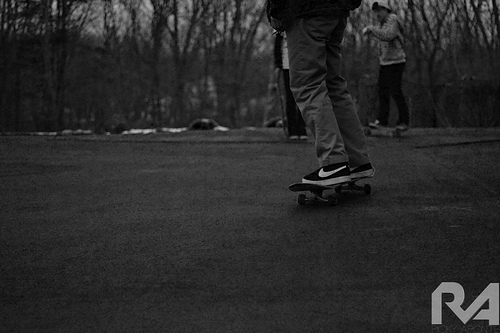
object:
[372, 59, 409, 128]
black pants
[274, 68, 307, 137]
pants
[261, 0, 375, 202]
men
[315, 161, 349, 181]
check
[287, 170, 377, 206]
skate board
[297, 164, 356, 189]
foot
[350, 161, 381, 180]
foot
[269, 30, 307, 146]
person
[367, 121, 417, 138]
skateboard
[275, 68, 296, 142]
skateboard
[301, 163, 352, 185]
shoes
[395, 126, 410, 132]
shoes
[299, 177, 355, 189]
bottom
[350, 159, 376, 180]
shoes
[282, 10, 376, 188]
pants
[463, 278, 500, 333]
letter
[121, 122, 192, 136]
snow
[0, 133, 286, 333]
ground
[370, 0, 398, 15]
cap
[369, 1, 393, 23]
head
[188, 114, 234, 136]
car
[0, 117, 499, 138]
road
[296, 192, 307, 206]
wheels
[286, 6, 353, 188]
legs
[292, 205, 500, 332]
ground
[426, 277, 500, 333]
corner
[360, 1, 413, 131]
boy